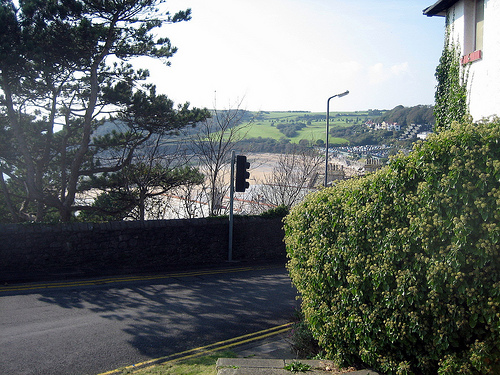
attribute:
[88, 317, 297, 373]
line — yellow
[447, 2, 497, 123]
wall — white 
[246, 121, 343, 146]
grass — Green 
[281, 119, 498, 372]
bush — Green 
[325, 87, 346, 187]
post — lamp